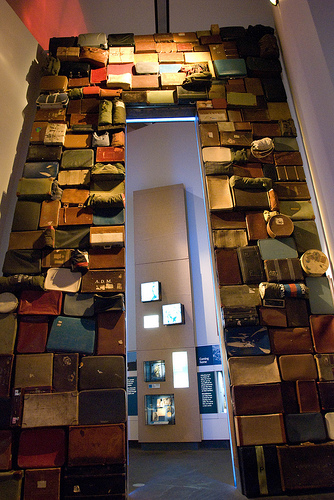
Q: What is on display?
A: There are many wallets on display.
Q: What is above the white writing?
A: There is a white wall.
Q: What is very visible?
A: There are big bricks that are visible.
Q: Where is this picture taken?
A: A museum.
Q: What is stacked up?
A: Luggage.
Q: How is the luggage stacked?
A: In an inverted u.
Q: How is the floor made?
A: Of stone.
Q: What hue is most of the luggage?
A: Brown.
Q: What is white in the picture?
A: The hallway.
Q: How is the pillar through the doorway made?
A: Of wood.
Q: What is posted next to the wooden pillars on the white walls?
A: Information boards.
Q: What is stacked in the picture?
A: Luggage.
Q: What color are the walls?
A: White.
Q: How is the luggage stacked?
A: On top of each other.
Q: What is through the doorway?
A: A hallway.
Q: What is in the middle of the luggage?
A: A doorway.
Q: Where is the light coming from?
A: The top.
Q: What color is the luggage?
A: Brown, red and blue.